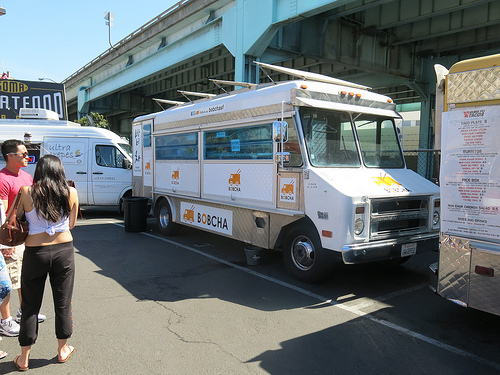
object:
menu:
[439, 104, 499, 242]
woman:
[6, 153, 80, 372]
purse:
[0, 185, 30, 247]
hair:
[35, 155, 67, 221]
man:
[0, 138, 46, 336]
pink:
[0, 168, 33, 216]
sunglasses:
[6, 152, 28, 155]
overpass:
[56, 1, 497, 180]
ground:
[115, 303, 435, 375]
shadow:
[243, 306, 499, 375]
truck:
[131, 59, 440, 284]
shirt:
[0, 167, 34, 217]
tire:
[280, 215, 336, 284]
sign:
[439, 103, 498, 243]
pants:
[17, 240, 75, 346]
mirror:
[272, 120, 287, 142]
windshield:
[296, 106, 406, 168]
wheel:
[278, 218, 335, 285]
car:
[1, 107, 134, 217]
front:
[93, 127, 133, 213]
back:
[27, 189, 74, 245]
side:
[130, 80, 273, 250]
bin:
[122, 196, 155, 233]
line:
[113, 224, 498, 373]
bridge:
[63, 1, 498, 187]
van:
[0, 107, 134, 215]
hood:
[311, 166, 439, 197]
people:
[1, 137, 80, 372]